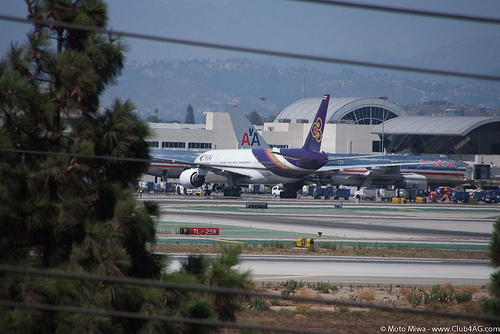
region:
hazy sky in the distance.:
[215, 15, 310, 35]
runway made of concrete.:
[312, 264, 425, 274]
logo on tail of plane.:
[307, 110, 327, 145]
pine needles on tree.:
[71, 205, 107, 248]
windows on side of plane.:
[217, 155, 247, 166]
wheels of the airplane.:
[275, 190, 300, 199]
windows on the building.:
[160, 140, 210, 150]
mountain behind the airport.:
[170, 68, 262, 83]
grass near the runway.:
[277, 314, 369, 328]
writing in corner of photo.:
[382, 323, 484, 332]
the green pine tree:
[4, 0, 262, 328]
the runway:
[213, 238, 493, 290]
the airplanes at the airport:
[168, 96, 480, 198]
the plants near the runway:
[281, 285, 471, 315]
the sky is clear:
[265, 4, 475, 37]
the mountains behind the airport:
[257, 20, 496, 105]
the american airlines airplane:
[211, 100, 488, 201]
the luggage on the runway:
[286, 181, 488, 207]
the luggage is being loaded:
[316, 177, 497, 217]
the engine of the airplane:
[166, 165, 221, 192]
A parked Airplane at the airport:
[111, 86, 369, 200]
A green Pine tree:
[1, 1, 223, 327]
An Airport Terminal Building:
[141, 100, 497, 167]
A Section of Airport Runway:
[184, 200, 499, 240]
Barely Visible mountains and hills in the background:
[123, 57, 492, 104]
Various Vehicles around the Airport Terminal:
[285, 185, 492, 205]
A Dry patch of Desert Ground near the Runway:
[276, 287, 471, 315]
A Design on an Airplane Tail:
[311, 115, 325, 142]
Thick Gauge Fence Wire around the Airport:
[1, 7, 498, 90]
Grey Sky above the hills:
[156, 5, 498, 42]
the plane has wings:
[129, 66, 497, 243]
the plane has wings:
[206, 91, 363, 318]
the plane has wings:
[99, 16, 421, 331]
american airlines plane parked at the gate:
[232, 100, 472, 197]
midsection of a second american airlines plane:
[142, 151, 208, 185]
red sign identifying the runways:
[183, 227, 220, 239]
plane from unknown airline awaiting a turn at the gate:
[147, 92, 334, 194]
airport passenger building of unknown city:
[74, 90, 499, 197]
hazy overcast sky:
[102, 0, 497, 70]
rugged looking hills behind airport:
[85, 32, 495, 118]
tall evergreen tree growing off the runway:
[0, 1, 244, 332]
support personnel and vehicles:
[307, 182, 496, 204]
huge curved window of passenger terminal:
[346, 105, 398, 121]